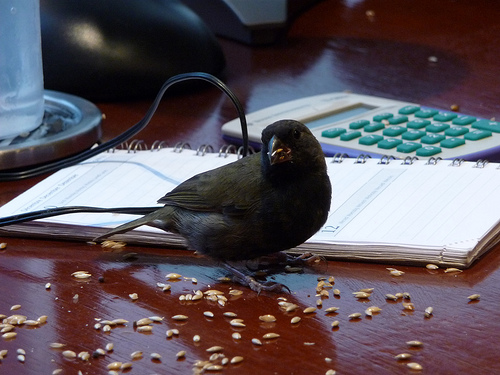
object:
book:
[4, 144, 500, 266]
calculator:
[219, 90, 499, 166]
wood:
[324, 286, 500, 372]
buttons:
[415, 145, 442, 157]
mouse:
[36, 2, 224, 108]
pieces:
[394, 350, 417, 361]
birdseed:
[398, 338, 426, 349]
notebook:
[0, 144, 500, 265]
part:
[162, 70, 233, 87]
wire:
[0, 70, 249, 182]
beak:
[266, 136, 294, 166]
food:
[39, 280, 57, 291]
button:
[321, 126, 348, 138]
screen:
[292, 101, 379, 132]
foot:
[241, 273, 293, 298]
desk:
[0, 0, 500, 373]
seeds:
[458, 290, 487, 305]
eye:
[290, 126, 306, 141]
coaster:
[0, 88, 105, 157]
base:
[223, 0, 306, 50]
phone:
[210, 0, 315, 54]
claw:
[281, 249, 329, 272]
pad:
[1, 146, 496, 266]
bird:
[81, 117, 329, 297]